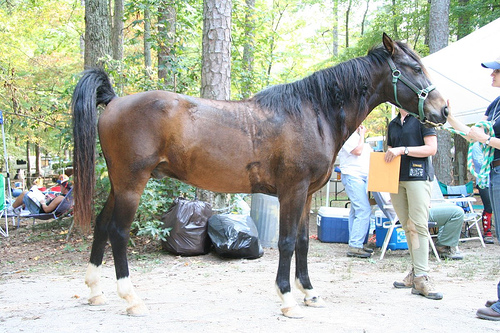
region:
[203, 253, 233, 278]
part of a ground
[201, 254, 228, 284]
par tof a ground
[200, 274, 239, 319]
part of a ground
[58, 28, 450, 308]
horse near people outside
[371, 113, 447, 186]
shirt on a woman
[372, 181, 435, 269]
pants on the woman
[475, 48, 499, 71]
hat on the person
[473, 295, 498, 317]
shoes on the person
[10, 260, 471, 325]
ground where horse stands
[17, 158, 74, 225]
people sitting in park area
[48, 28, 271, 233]
trunks of trees behind horse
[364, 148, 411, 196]
envelope on woman's hands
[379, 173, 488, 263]
chairs near the horse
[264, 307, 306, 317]
part of a hoof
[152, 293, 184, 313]
part of a ground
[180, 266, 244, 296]
part of a ground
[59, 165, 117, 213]
part of a tail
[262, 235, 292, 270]
part if a knee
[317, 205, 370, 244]
blue cooler with a white lid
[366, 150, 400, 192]
large manila envelope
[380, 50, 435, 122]
green bridle on the horse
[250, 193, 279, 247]
silver metal garbage can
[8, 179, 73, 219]
person sitting in a round chair reading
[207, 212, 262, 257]
black garbage bag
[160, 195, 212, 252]
larger garbage bag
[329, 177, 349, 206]
small section of folding table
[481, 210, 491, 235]
red sock with white dots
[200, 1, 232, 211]
large tree trunk behind the horse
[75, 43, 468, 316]
this is a horse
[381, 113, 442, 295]
this is a man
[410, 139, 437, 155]
the man is light skinned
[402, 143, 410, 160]
this is a watch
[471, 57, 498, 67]
this is a cap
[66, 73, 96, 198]
this is the tail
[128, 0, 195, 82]
this is a tree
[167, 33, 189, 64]
the leaves are green in color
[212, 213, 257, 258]
this is a paper bag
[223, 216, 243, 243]
the bag is black in color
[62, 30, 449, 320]
large brown and black horse with white hooves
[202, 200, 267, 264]
full black plastic trash bag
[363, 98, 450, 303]
person holding manila envelope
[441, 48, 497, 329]
girl holding rope bridle of horse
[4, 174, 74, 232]
man reading in lawn chair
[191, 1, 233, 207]
tall tree trunk behind trash bags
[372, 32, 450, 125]
green bridal on horse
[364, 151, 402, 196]
brown envelope in mans hand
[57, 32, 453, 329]
large brown horse standing by woman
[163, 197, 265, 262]
two trash bags behind horse